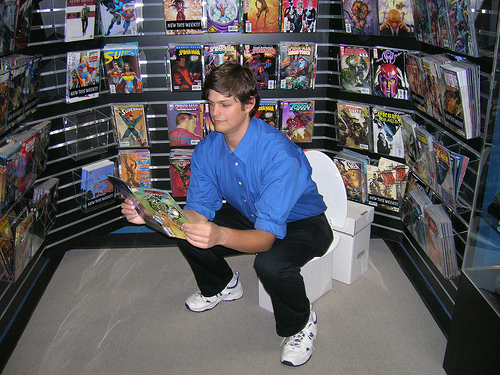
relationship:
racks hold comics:
[0, 1, 499, 307] [332, 1, 481, 281]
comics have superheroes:
[332, 1, 481, 281] [372, 60, 402, 97]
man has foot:
[121, 56, 332, 368] [281, 310, 320, 369]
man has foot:
[121, 56, 332, 368] [181, 271, 245, 313]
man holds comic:
[121, 56, 332, 368] [104, 171, 191, 240]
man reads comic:
[121, 56, 332, 368] [104, 171, 191, 240]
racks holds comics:
[0, 1, 499, 307] [332, 1, 481, 281]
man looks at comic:
[121, 56, 332, 368] [104, 171, 191, 240]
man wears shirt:
[121, 56, 332, 368] [179, 115, 330, 237]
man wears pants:
[121, 56, 332, 368] [173, 197, 333, 335]